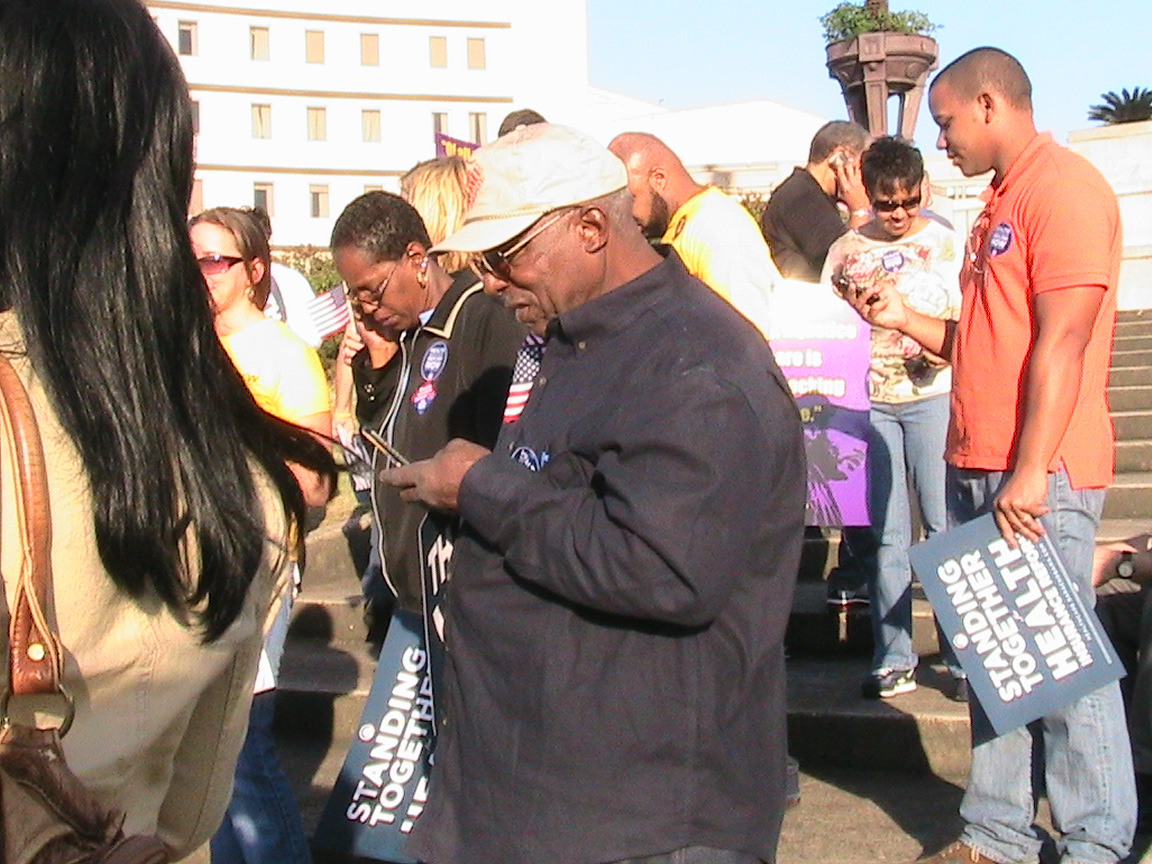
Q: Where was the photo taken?
A: An event.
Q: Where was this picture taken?
A: Steps.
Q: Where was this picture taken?
A: On the street.